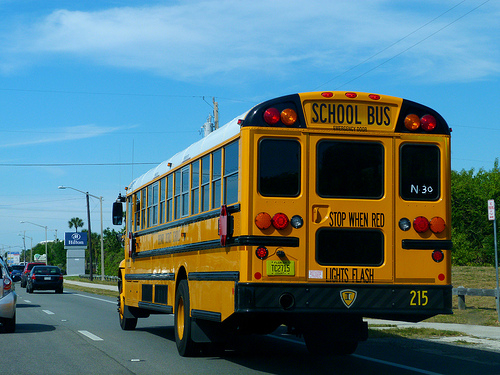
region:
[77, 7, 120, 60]
part of a cloud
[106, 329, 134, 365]
part of a road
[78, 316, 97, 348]
par of a line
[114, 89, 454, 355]
school bus driving down the road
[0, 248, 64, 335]
alot of traffic on the road moving slow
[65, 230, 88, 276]
sign by the road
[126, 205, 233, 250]
stop signs on side of the bus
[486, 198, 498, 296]
no parking sign in grass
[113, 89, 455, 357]
yellow automobile carrying children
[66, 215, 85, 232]
palm tree growing by road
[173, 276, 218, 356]
inside of wheel is painted yellow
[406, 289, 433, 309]
bus number for identification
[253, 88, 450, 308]
caution lights and signs on back of the bus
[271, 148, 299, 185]
part of a window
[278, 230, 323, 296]
part pof a bus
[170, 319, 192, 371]
part of a wheel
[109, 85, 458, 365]
A yellow and black school bus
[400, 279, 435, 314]
Bus number is 215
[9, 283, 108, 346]
White lines on the street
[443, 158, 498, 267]
Green leaves on a tree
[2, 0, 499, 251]
White clouds in the sky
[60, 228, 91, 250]
A blue colored sign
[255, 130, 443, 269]
Windows on back of the bus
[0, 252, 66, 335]
Cars in the street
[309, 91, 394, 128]
The words "SCHOOL BUS" on bus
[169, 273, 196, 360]
A black round tire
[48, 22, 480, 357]
bus moving along the road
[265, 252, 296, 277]
license plate of the vehicle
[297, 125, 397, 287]
back door with words of caution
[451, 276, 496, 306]
short wooden fence along the grass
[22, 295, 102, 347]
white lines down the middle of the street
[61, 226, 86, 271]
logo and sign for the Hilton Hotel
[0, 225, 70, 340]
group of cars driving in the same direction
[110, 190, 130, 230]
driver's side mirror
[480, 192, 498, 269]
no parking sign on a pole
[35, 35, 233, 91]
a few clouds in an otherwise blue sky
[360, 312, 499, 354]
a concrete sidewalk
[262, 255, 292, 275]
a yellow license plate on a bus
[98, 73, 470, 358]
School Bus on highway.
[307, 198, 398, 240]
Back door "Stop When Red".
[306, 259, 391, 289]
Bottom door "Lights Flash".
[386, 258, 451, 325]
Bumper bus number 215.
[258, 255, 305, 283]
Green license plate TC2715.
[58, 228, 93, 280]
Hilton Hotel roadside sign.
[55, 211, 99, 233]
Palm tree above sign.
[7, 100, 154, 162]
White cloud streak blue sky.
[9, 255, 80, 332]
Highway traffic before bus.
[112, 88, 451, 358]
school bus on road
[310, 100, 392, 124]
the text is black